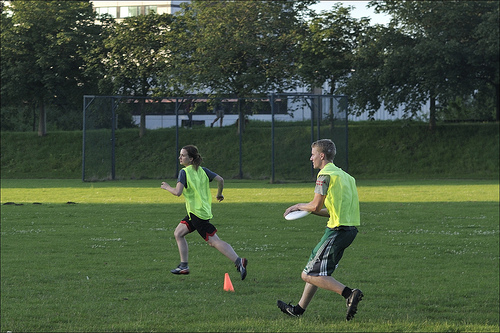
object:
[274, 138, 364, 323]
man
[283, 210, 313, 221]
frisbee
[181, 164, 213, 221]
top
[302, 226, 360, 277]
shorts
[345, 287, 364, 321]
shoe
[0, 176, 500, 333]
field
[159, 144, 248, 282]
woman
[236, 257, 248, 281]
foot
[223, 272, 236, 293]
boundary marker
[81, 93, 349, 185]
goal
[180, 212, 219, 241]
shorts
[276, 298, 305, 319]
cleat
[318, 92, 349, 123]
fence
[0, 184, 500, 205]
sunlight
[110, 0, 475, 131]
building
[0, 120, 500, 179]
hill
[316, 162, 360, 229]
vest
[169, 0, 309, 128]
tree